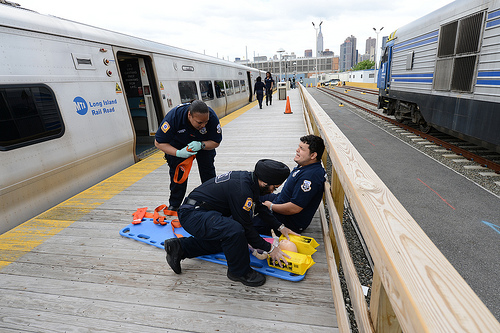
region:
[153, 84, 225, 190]
paramedic with blue gloves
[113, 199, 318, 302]
body board on ground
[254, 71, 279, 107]
woman and girl walking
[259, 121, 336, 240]
man hurt on ground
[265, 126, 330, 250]
hurt man on ground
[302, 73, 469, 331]
wooden divider between trains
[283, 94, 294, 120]
orange cone on ground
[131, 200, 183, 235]
orange straps on blue board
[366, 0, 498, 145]
blue and gray train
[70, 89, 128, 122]
blue logo on train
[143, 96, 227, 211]
Woman wearing a blue uniform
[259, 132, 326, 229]
Man sitting on the ground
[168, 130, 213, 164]
Gloves on the woman's hand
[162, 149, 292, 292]
Man kneeling on the ground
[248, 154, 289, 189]
Turban on the man's head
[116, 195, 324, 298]
Blue board on the ground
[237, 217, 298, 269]
Doll on the board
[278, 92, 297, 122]
Cone on the ground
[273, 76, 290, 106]
Trashcan in the background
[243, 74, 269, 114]
Lady walking on the platform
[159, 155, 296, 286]
Man wearing black turban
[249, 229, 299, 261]
Doll baby on blue life board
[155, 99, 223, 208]
Person wearing blue gloves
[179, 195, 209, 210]
Black belt on pants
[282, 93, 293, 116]
Orange cone next to wooden rail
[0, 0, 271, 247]
Silver train next to person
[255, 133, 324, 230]
Man is leaning against wooden rail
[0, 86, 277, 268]
Yellow line painted next to train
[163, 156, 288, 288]
Man wearing blue pants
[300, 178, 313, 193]
Patch on blue shirt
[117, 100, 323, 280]
Emergency medical care practice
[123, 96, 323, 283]
Practice medical care on baby doll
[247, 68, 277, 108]
People walking by a stopped train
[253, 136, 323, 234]
Emergency worker in pain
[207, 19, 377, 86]
City in the distance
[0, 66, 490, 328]
Wooden train platform with railing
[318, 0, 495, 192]
Silver and blue train on tracks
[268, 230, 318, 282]
Yellow head supports medical training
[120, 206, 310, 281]
Blue backboard used in medical training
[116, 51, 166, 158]
Stopped train's door left open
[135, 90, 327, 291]
paramedics on the ground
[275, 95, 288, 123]
orange cone on the ground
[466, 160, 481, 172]
cross tie on the track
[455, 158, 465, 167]
cross tie on the track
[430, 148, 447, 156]
cross tie on the track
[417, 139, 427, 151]
cross tie on the track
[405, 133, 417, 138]
cross tie on the track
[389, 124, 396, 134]
cross tie on the track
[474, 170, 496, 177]
cross tie on the track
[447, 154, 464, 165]
cross tie on the track